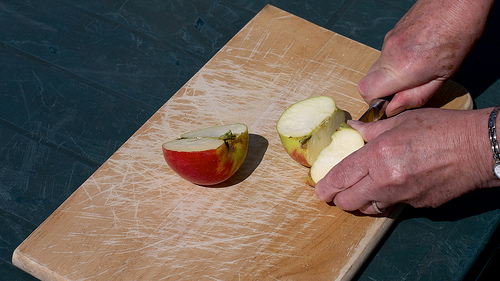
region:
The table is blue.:
[1, 1, 499, 279]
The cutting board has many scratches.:
[13, 12, 478, 279]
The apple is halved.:
[161, 115, 263, 197]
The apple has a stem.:
[163, 113, 264, 201]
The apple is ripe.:
[157, 120, 262, 183]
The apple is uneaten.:
[153, 108, 258, 190]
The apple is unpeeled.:
[144, 110, 264, 195]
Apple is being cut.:
[271, 2, 499, 234]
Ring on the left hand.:
[276, 2, 499, 224]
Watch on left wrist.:
[276, 1, 499, 234]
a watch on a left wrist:
[474, 95, 499, 184]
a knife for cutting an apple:
[326, 71, 412, 143]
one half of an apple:
[156, 114, 255, 191]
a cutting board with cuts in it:
[11, 11, 471, 273]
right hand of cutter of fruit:
[355, 2, 482, 124]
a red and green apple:
[143, 112, 265, 200]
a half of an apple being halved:
[269, 85, 376, 206]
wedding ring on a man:
[357, 191, 393, 221]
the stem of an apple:
[211, 120, 247, 158]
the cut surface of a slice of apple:
[277, 92, 336, 142]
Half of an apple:
[161, 119, 258, 189]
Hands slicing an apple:
[275, 14, 487, 226]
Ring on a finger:
[358, 195, 394, 217]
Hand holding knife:
[353, 16, 470, 143]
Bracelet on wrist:
[482, 95, 498, 180]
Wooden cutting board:
[12, 2, 479, 278]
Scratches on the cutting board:
[106, 167, 202, 236]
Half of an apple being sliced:
[275, 92, 372, 188]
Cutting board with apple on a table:
[8, 0, 483, 271]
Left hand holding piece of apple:
[303, 95, 497, 225]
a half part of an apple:
[154, 99, 269, 200]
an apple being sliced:
[268, 78, 397, 214]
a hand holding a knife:
[339, 0, 444, 120]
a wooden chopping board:
[10, 138, 114, 279]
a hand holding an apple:
[312, 125, 445, 238]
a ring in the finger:
[361, 193, 393, 225]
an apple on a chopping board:
[73, 48, 278, 227]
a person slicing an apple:
[272, 10, 499, 239]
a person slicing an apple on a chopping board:
[271, 15, 483, 248]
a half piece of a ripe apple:
[55, 93, 274, 201]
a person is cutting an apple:
[280, 60, 430, 220]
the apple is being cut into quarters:
[276, 95, 391, 198]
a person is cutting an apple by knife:
[341, 63, 404, 140]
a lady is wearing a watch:
[470, 98, 498, 181]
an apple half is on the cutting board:
[155, 120, 251, 190]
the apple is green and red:
[157, 120, 252, 185]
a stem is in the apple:
[210, 125, 240, 150]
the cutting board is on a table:
[5, 5, 486, 278]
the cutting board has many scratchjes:
[70, 33, 355, 278]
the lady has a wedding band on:
[365, 192, 395, 223]